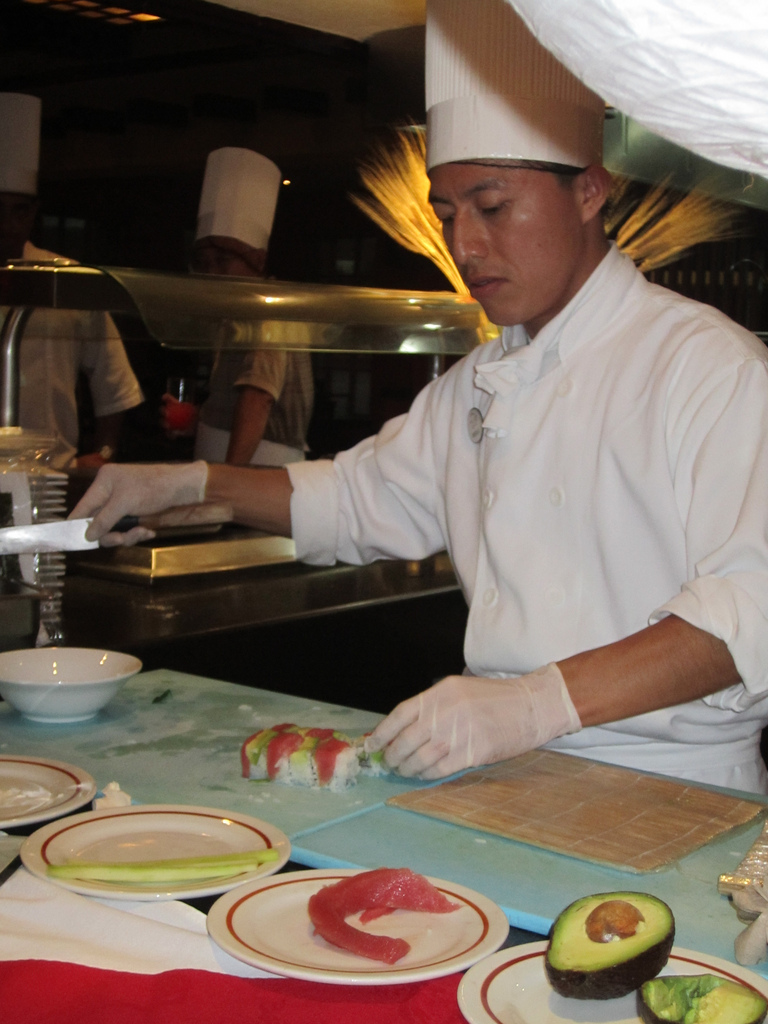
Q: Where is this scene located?
A: In a restaurant kitchen.